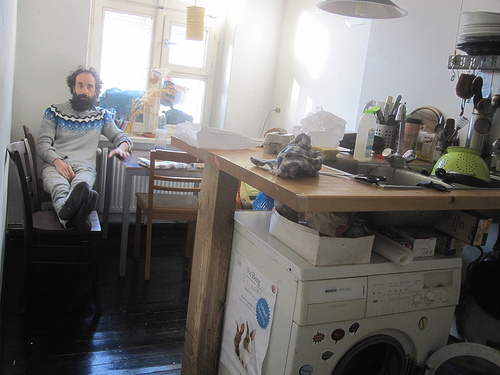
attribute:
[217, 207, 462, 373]
washing machine — white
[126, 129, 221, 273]
chair — brown, wooden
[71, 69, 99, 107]
face — bearded, man's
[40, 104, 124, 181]
sweater — gray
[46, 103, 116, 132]
design — blue, white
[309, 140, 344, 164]
sponge — yellow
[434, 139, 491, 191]
strainer — green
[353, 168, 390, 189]
handles — black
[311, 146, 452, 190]
sink — silver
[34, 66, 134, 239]
man — sitting 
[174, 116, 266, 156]
plastic bag — white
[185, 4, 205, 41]
light — hanging 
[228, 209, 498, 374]
washer — white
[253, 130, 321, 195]
rag — white, blue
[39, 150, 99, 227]
legs — extended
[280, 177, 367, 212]
counter — wooden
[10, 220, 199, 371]
floor — Black , hardwood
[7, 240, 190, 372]
flooring — dark, wood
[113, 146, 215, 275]
table — little, square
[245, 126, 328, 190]
cloth — on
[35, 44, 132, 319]
man — wearing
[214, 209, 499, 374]
washing machine — white, portable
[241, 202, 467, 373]
laundry machine — white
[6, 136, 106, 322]
chair — dark brown, wooden 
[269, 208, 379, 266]
box — white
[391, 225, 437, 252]
box — white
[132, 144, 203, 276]
chair — light brown, wooden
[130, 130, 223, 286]
chair — wooden, empty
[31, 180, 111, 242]
feet — resting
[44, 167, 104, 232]
legs — up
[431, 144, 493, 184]
colander — green